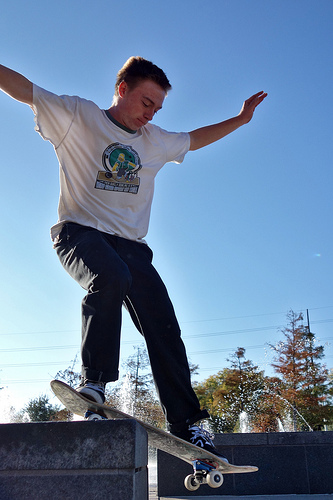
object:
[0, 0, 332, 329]
sky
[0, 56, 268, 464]
boy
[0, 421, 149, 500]
wall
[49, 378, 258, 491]
skateboard